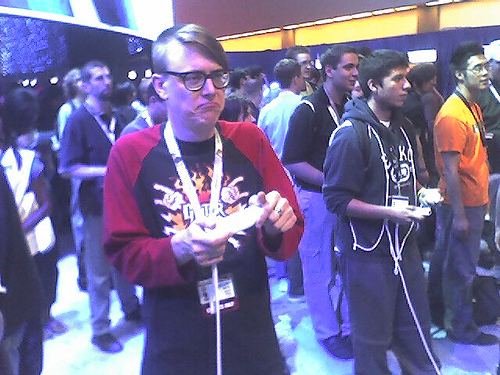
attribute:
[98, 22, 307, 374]
man — standing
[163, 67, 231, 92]
glasses — black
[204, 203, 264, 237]
controller — white, remote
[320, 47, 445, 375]
man — standing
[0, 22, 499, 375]
people — standing, players, crowd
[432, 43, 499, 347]
man — standing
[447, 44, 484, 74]
hair — black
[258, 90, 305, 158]
shirt — white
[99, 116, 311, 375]
shirt — black, red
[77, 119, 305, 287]
sleeves — red, long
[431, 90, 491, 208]
shirt — orange, short sleeved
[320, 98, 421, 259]
hoodie — dark, black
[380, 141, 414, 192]
print — white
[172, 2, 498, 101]
wall — brown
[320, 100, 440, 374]
clothing — dark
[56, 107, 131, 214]
shirt — black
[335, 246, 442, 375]
pants — black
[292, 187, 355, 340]
pants — blue